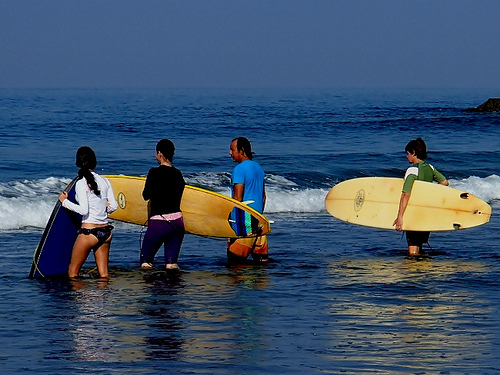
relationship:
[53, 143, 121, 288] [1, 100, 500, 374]
woman in water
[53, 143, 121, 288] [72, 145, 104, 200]
woman has hair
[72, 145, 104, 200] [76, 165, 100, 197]
hair in ponytail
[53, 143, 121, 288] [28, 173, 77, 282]
woman holding surfboard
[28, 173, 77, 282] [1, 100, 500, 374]
surfboard in water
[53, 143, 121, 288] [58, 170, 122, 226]
woman wears shirt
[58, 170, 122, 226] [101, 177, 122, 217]
shirt has sleeve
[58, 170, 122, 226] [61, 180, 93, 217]
shirt has sleeve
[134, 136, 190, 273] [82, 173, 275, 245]
woman holding surfboard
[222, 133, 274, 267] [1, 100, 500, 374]
man in water